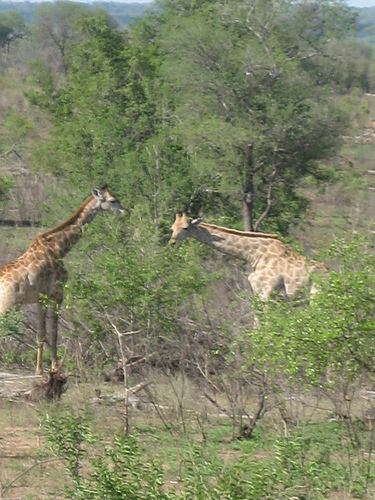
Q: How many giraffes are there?
A: 2.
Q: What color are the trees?
A: Green.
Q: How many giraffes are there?
A: Two.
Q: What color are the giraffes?
A: Brown and white.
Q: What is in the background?
A: Trees.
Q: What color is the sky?
A: Blue.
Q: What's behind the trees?
A: Sky.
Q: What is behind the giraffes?
A: Trees.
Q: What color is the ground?
A: Brown.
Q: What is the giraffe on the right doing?
A: Bending.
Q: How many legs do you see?
A: Two.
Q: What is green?
A: Leafs.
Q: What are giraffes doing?
A: Grazing.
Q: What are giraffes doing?
A: Standing.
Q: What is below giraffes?
A: Dead trees and bushes.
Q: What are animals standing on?
A: Grass and dirt.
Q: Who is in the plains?
A: Two giraffes.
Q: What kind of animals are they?
A: Giraffes.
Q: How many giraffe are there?
A: 2.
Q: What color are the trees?
A: Green.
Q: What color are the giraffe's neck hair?
A: Brown.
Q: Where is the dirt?
A: On the ground with the grass.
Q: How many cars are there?
A: None.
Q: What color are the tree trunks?
A: Brown.